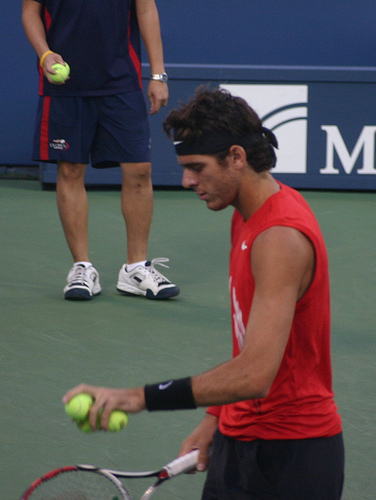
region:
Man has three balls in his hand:
[62, 382, 130, 434]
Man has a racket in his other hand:
[15, 448, 205, 499]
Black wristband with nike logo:
[143, 378, 196, 411]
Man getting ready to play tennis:
[24, 91, 354, 497]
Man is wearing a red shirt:
[210, 185, 342, 436]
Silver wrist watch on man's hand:
[148, 73, 167, 79]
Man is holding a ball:
[42, 58, 69, 84]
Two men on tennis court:
[17, 0, 345, 499]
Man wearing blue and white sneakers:
[60, 261, 181, 299]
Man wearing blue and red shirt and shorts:
[35, 0, 153, 164]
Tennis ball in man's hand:
[44, 60, 72, 82]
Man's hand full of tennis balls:
[62, 382, 143, 434]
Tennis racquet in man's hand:
[13, 447, 205, 498]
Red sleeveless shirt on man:
[195, 180, 341, 439]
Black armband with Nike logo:
[146, 379, 200, 411]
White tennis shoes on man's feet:
[63, 263, 181, 299]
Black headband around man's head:
[171, 126, 285, 155]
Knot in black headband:
[260, 124, 289, 148]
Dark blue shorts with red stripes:
[37, 94, 161, 161]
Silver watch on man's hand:
[148, 72, 167, 80]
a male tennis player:
[62, 89, 345, 498]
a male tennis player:
[20, 0, 180, 301]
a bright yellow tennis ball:
[65, 390, 94, 419]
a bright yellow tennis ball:
[103, 409, 125, 431]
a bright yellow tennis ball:
[74, 415, 93, 432]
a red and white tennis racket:
[20, 450, 196, 498]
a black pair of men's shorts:
[206, 427, 344, 496]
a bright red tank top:
[219, 181, 342, 440]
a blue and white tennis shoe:
[62, 260, 101, 299]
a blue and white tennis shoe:
[114, 255, 180, 299]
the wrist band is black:
[142, 377, 208, 421]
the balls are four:
[62, 396, 136, 436]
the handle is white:
[166, 445, 200, 489]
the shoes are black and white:
[123, 256, 188, 307]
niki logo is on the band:
[153, 375, 179, 396]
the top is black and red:
[44, 14, 149, 85]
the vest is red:
[222, 220, 335, 435]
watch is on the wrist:
[137, 65, 181, 88]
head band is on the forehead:
[164, 118, 275, 152]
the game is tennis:
[4, 3, 362, 498]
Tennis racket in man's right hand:
[1, 413, 218, 498]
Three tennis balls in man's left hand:
[67, 376, 133, 434]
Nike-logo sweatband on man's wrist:
[143, 373, 195, 413]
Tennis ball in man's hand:
[38, 47, 69, 86]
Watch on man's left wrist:
[151, 64, 169, 86]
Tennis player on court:
[17, 88, 350, 495]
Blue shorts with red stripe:
[37, 43, 152, 165]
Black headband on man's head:
[168, 125, 276, 152]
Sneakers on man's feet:
[63, 256, 179, 302]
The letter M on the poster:
[320, 121, 375, 177]